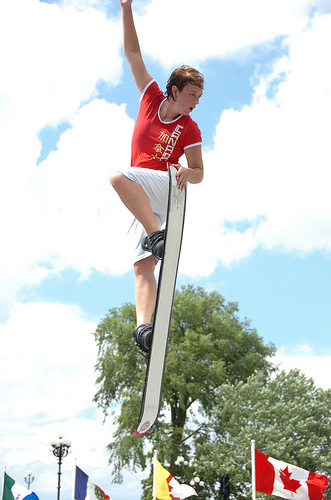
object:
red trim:
[126, 427, 153, 435]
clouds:
[0, 0, 123, 141]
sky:
[255, 254, 329, 328]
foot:
[132, 322, 153, 353]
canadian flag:
[249, 439, 327, 499]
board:
[133, 165, 187, 438]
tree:
[191, 366, 331, 500]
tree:
[91, 283, 278, 500]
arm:
[121, 10, 153, 96]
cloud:
[128, 0, 311, 69]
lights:
[46, 432, 70, 471]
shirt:
[130, 79, 203, 170]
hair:
[165, 65, 206, 103]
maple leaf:
[278, 466, 303, 493]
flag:
[267, 456, 312, 498]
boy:
[108, 0, 204, 358]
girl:
[108, 0, 205, 354]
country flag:
[150, 452, 199, 500]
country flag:
[74, 464, 112, 500]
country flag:
[0, 467, 40, 500]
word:
[149, 130, 169, 160]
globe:
[50, 436, 72, 458]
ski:
[134, 166, 187, 437]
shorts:
[119, 167, 171, 266]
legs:
[133, 211, 158, 323]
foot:
[141, 229, 166, 260]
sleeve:
[182, 120, 202, 150]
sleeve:
[139, 78, 159, 103]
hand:
[171, 163, 189, 191]